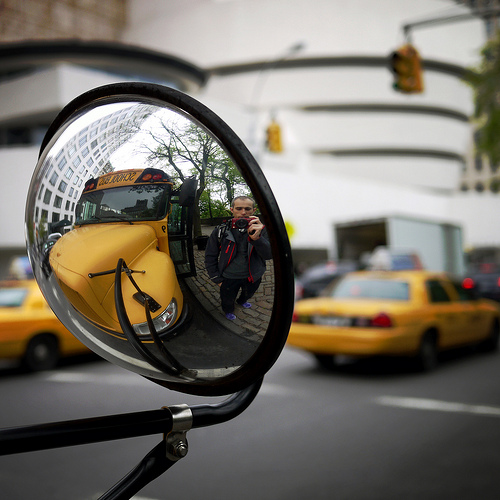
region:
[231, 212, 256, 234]
Man holding a camera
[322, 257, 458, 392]
Yellow taxi in the street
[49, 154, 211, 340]
Yellow school bus in the mirror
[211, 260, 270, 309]
Man wearing black pants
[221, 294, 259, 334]
Man wearing blue sneakers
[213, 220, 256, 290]
Man wearing a black jacket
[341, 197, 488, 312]
White truck on the street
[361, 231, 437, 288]
advertisement on a taxi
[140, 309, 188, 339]
head lights on a school bus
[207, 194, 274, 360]
man holding a camera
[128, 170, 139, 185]
the backwards letter S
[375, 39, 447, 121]
a yellow traffic light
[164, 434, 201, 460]
a single metal bolt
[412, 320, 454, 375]
the back taxi tire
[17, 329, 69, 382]
tire on a cab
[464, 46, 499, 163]
these are green leaves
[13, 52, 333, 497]
this is the mirror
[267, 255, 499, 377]
this is a taxi cab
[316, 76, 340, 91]
this is the color white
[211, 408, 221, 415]
this is the color black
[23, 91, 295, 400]
a round mirror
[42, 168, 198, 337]
a reflection of a school bus in the mirror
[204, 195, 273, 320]
a reflection of the photographer in the mirror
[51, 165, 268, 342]
a reflection of the guy and bus in the mirror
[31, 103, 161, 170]
a reflection of the building in the mirror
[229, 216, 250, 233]
a reflection of the camera in the mirror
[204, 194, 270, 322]
a guy holding a camera in the mirror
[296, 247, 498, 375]
a yellow car in the background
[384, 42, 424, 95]
a traffic light in the background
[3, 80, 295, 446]
a side mirror with a reflection of the bus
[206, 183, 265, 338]
A reflection of a man with a camera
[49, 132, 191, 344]
A reflection of a yellow school bus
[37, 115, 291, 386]
A large rearview mirror that is round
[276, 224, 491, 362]
A yellow cab with brakes on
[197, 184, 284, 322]
The man is wearing blue sneakers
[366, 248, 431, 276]
The sign on top of a cab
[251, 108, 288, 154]
A traffic signal overhead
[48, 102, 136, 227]
A tall building in a mirror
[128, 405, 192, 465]
Silver and black metal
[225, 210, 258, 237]
A camera that is red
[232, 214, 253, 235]
a black picture taking device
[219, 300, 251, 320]
a pair of blue shoes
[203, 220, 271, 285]
a dark grey jacket with red trim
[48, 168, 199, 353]
a large yellow school bus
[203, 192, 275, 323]
a guy taking a picture in the relfection of a mirror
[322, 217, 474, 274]
an open trail on a large truck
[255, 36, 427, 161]
a pair of yellow traffic signals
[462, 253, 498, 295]
back of a mid-size SUV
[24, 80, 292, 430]
a rounded rearview school bus mirror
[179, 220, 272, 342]
a color bricked sidewalk